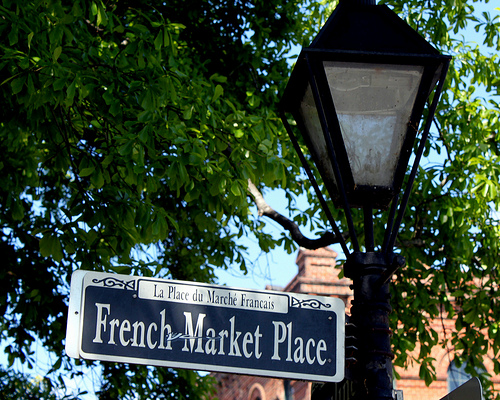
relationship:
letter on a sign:
[132, 320, 150, 352] [57, 264, 347, 386]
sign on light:
[70, 255, 358, 394] [264, 10, 438, 214]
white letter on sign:
[87, 281, 346, 372] [52, 253, 354, 377]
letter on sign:
[272, 318, 288, 369] [57, 264, 347, 386]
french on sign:
[93, 297, 173, 355] [79, 273, 344, 382]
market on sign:
[179, 311, 267, 359] [79, 273, 344, 382]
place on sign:
[267, 321, 328, 364] [79, 273, 344, 382]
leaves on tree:
[149, 39, 238, 132] [4, 4, 485, 396]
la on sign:
[152, 281, 164, 299] [79, 273, 344, 382]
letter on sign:
[153, 304, 173, 351] [57, 264, 347, 386]